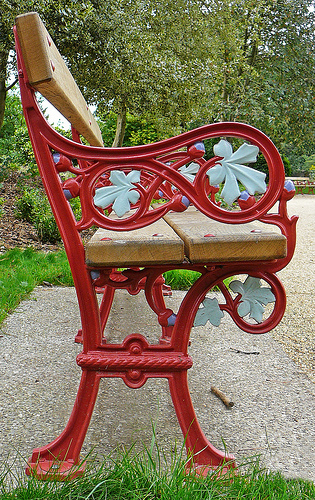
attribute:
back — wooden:
[19, 15, 99, 131]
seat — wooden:
[86, 224, 292, 263]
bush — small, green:
[13, 191, 51, 238]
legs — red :
[22, 263, 287, 489]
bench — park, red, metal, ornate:
[7, 11, 300, 482]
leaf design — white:
[190, 272, 278, 329]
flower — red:
[168, 194, 189, 212]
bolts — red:
[84, 220, 242, 254]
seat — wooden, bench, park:
[66, 130, 273, 301]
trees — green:
[114, 1, 312, 96]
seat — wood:
[87, 200, 290, 270]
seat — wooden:
[86, 204, 285, 263]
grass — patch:
[4, 250, 63, 291]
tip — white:
[164, 312, 177, 327]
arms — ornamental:
[36, 104, 297, 236]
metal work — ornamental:
[9, 26, 297, 479]